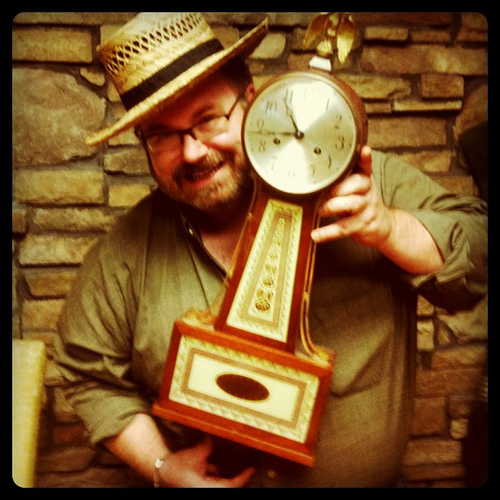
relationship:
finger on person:
[190, 466, 256, 489] [53, 13, 487, 489]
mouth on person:
[176, 157, 226, 189] [53, 13, 487, 489]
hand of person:
[157, 446, 254, 491] [53, 13, 487, 489]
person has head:
[53, 13, 487, 489] [119, 32, 268, 241]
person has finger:
[88, 35, 271, 347] [172, 439, 231, 473]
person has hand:
[53, 13, 487, 489] [305, 140, 410, 252]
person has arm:
[53, 13, 487, 489] [336, 130, 493, 321]